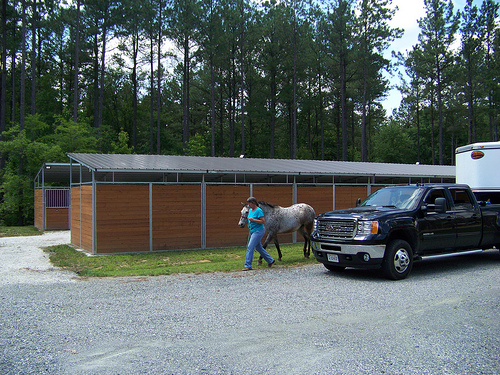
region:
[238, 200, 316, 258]
A white horse on the grass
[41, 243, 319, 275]
A small grassy area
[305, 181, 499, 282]
A large parked truck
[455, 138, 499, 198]
A trailer attached to the truck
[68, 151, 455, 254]
A set of wooden pins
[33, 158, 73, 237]
A horse pin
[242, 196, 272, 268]
A person in a blue shirt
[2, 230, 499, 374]
Some gravel on the ground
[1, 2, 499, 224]
A large forested area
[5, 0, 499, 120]
A clear blue sky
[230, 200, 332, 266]
man walking horse by truck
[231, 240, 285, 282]
denim blue jeans on man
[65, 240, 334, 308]
short green grass around building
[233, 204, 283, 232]
light blue shirt on woman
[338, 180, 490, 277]
black gmc pickup truck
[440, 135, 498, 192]
white horse camper on truck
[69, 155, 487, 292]
brown wooden horse stables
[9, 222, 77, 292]
small rocky path by stables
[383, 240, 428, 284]
black rubber tire on truck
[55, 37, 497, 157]
tall green trees by stable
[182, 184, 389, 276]
woman walking horse on grass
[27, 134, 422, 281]
horse stalls for horses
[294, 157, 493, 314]
four-door black pickup truck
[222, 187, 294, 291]
woman wearing blue shirt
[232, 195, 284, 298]
woman wearing blue jeans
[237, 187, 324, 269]
white and brown speckled horse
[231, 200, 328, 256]
brown mane on horse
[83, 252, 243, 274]
dirt spots in grass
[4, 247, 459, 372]
gravel on dirt road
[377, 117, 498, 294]
pickup truck pulling horse trailer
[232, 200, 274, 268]
a person leading a horse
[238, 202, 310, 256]
a gray and white horse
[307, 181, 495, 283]
a black pickup truck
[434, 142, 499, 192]
the top of a white trailer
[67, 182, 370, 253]
a long wooden enclosure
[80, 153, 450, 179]
a long metal roof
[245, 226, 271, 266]
a pair of blue jeans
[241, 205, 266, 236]
a light blue t-shirt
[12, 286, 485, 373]
an open gravel driveway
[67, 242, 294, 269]
a patch of green grass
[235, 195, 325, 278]
a person with a horse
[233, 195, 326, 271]
a person walking a horse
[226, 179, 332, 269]
a person leads a horse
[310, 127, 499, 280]
a truck pulling a horse trailer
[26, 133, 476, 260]
a barn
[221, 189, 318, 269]
the person with the horse is wearing blue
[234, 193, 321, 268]
the horse is spotted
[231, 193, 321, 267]
the horse is white with brown spots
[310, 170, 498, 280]
the truck is black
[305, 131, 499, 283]
the truck is pulling a white trailer